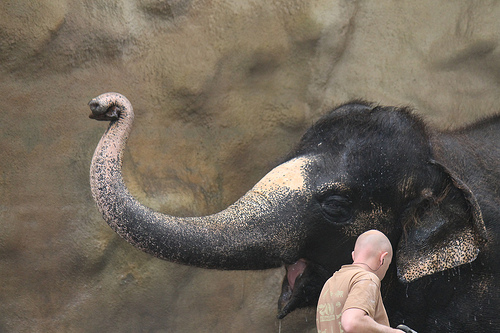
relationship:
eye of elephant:
[319, 192, 354, 223] [70, 78, 499, 330]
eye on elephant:
[321, 189, 360, 222] [70, 78, 499, 330]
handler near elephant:
[315, 226, 408, 331] [70, 78, 499, 330]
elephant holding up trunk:
[70, 78, 499, 330] [87, 85, 322, 273]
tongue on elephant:
[281, 252, 301, 286] [70, 78, 499, 330]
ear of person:
[379, 252, 387, 265] [300, 215, 417, 332]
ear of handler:
[364, 247, 391, 273] [315, 229, 409, 333]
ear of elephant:
[401, 161, 485, 286] [70, 78, 499, 330]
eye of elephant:
[319, 192, 354, 223] [75, 74, 486, 309]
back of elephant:
[432, 116, 494, 182] [70, 78, 499, 330]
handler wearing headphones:
[315, 229, 409, 333] [372, 244, 385, 278]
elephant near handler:
[70, 78, 499, 330] [306, 220, 412, 330]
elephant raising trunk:
[70, 78, 499, 330] [81, 87, 300, 271]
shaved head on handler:
[351, 227, 395, 282] [315, 229, 409, 333]